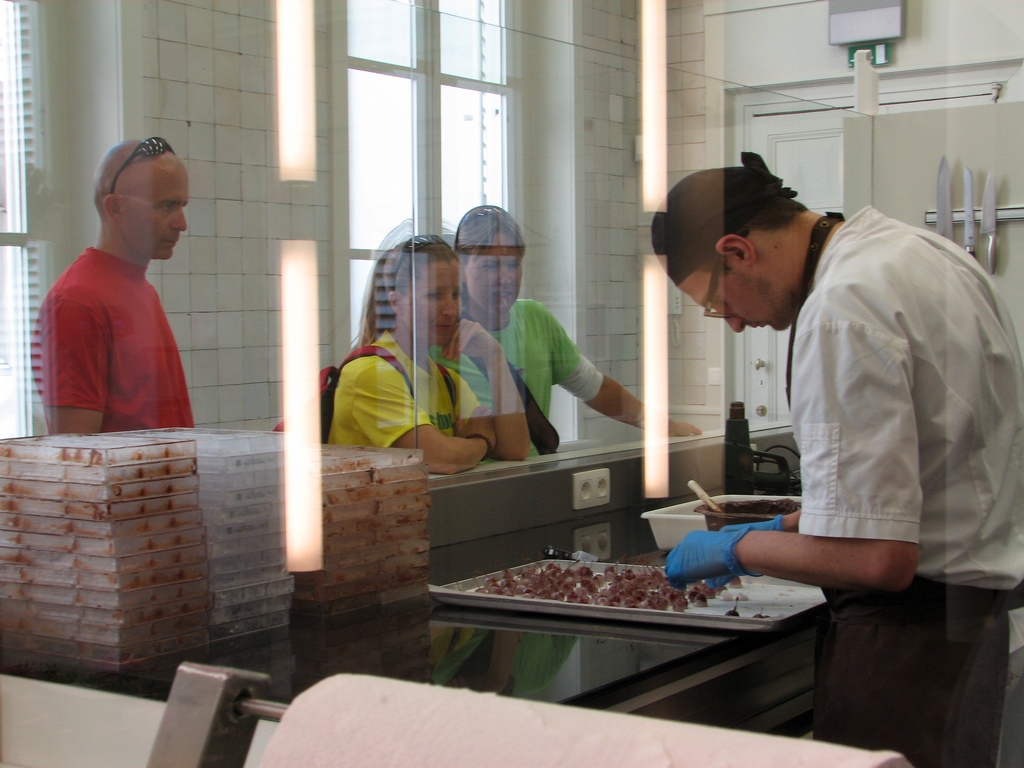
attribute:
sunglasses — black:
[684, 268, 733, 335]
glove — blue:
[655, 522, 767, 583]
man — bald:
[648, 152, 1004, 760]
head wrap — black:
[643, 154, 830, 276]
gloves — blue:
[658, 505, 785, 595]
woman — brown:
[435, 199, 699, 457]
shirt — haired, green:
[446, 302, 611, 451]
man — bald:
[29, 130, 208, 435]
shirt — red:
[33, 244, 189, 428]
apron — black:
[748, 209, 1021, 672]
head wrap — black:
[643, 157, 815, 282]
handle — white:
[683, 477, 718, 512]